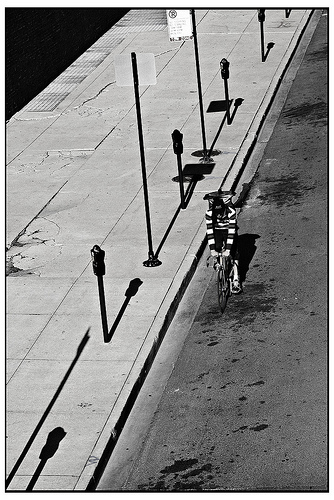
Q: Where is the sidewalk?
A: To his right.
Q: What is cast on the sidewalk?
A: Shadow.